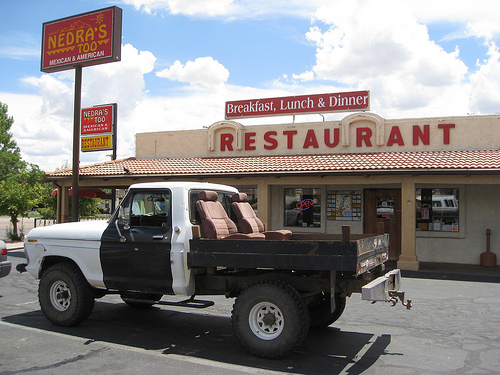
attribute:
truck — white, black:
[18, 175, 417, 357]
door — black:
[100, 219, 173, 292]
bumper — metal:
[361, 267, 403, 308]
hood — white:
[25, 213, 108, 247]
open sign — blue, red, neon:
[293, 195, 317, 215]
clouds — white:
[301, 9, 487, 106]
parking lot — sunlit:
[1, 247, 499, 374]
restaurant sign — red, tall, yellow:
[40, 3, 121, 76]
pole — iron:
[69, 68, 81, 225]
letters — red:
[216, 122, 457, 150]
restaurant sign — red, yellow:
[74, 102, 116, 135]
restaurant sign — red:
[218, 90, 375, 116]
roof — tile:
[40, 153, 499, 182]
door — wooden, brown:
[360, 184, 404, 263]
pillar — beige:
[392, 181, 421, 271]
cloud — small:
[154, 55, 233, 89]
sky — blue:
[150, 22, 291, 56]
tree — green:
[0, 99, 52, 242]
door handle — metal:
[153, 233, 168, 240]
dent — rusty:
[170, 254, 177, 269]